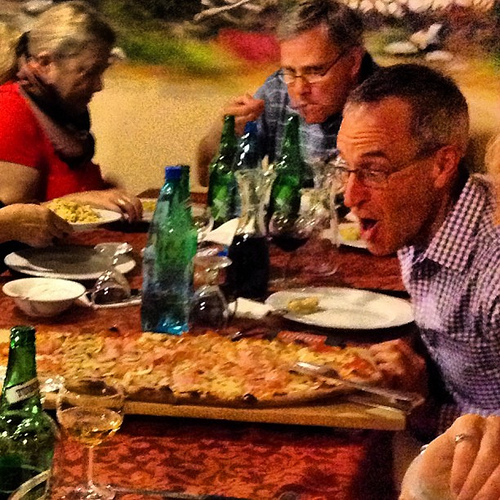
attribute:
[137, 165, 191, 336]
bottle — plastic, blue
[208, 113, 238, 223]
bottle — glass, green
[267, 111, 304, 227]
bottle — glass, green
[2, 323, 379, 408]
pizza — large, whole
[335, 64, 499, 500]
man — amazed, white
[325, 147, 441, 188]
glasses — square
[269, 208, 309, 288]
glass — full, clear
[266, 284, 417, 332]
plate — empty, white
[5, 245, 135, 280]
plate — white, empty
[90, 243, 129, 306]
glass — upside down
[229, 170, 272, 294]
carafe — half filled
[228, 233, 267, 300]
wine — red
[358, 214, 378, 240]
mouth — open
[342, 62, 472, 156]
hair — short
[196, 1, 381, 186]
man — eating, white, feasting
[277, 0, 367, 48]
hair — short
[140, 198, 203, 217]
plate — white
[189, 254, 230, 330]
glass — clear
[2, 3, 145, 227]
lady — white, old